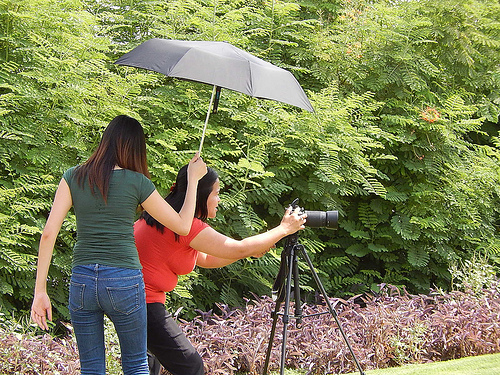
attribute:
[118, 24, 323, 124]
umberella — black 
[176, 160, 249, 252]
woman — looking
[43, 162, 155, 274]
shirt — red 